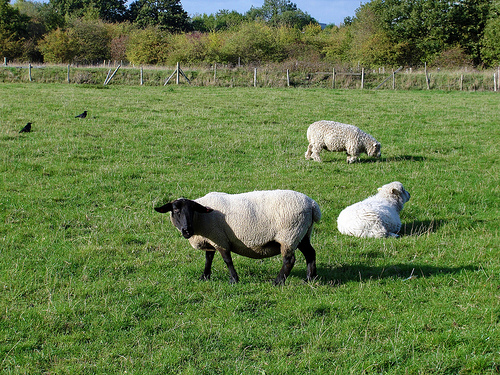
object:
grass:
[0, 81, 500, 374]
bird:
[18, 122, 32, 134]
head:
[153, 196, 214, 239]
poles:
[175, 61, 180, 84]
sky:
[289, 0, 372, 28]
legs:
[204, 226, 241, 285]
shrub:
[206, 17, 278, 64]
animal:
[153, 188, 322, 286]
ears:
[154, 202, 173, 213]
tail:
[312, 200, 323, 225]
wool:
[254, 223, 279, 233]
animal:
[335, 180, 412, 241]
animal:
[304, 119, 384, 165]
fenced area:
[0, 80, 500, 375]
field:
[0, 81, 500, 375]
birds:
[74, 110, 89, 119]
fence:
[25, 61, 498, 93]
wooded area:
[0, 8, 500, 71]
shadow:
[288, 262, 477, 289]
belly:
[224, 224, 280, 261]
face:
[169, 198, 198, 239]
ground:
[0, 80, 500, 375]